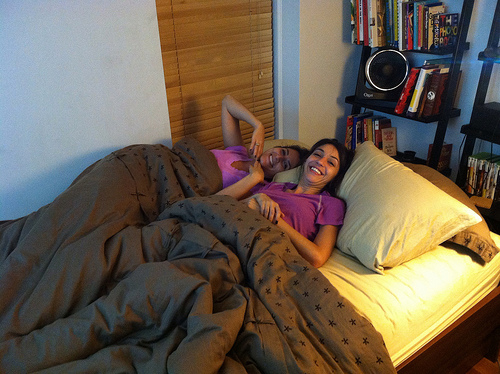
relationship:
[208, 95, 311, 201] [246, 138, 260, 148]
lady wearing ring